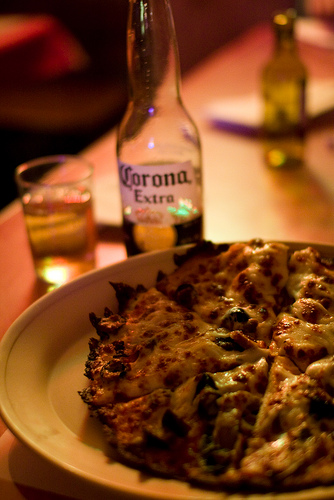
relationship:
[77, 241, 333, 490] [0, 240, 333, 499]
pizza on top of plate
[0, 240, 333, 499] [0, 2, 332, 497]
plate on top of counter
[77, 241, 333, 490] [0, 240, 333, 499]
pizza sitting on plate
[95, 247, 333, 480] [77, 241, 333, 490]
cheese on top of pizza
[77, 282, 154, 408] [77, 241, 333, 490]
crust on edge of pizza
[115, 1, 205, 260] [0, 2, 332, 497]
bottle sitting on counter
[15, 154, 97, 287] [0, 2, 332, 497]
cup sitting on counter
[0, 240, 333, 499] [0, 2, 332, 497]
plate sitting on counter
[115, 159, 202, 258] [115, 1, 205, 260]
label on side of bottle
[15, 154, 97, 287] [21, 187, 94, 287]
cup filled with drink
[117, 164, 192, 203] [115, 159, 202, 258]
writing on front of label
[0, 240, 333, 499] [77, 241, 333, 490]
plate has pizza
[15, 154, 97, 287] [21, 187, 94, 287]
cup has drink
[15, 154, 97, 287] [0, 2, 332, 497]
cup on top of counter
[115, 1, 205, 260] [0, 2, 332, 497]
bottle on top of counter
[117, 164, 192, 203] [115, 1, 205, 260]
writing on front of bottle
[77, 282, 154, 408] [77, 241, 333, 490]
crust on side of pizza